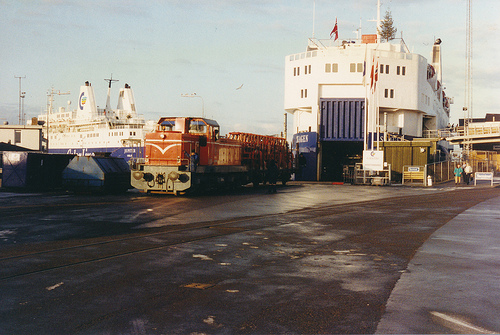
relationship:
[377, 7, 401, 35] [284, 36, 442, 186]
tree on building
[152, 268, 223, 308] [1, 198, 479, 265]
line on road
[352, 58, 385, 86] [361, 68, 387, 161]
flags on poles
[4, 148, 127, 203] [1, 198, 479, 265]
dumpsters on road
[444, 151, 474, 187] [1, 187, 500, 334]
people in road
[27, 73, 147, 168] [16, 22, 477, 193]
boat in background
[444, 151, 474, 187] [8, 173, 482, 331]
people on street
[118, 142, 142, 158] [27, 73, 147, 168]
name of boat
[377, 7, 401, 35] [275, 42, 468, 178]
tree on ship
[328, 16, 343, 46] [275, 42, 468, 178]
flag on ship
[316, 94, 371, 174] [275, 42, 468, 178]
door on ship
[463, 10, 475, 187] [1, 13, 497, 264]
tower in harbor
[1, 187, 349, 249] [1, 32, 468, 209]
shadows of ships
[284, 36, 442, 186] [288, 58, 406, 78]
building has windows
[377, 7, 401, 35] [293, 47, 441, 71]
tree on roof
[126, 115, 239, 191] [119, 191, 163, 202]
train on tracks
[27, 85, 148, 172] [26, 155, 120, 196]
boat in water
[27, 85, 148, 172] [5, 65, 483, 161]
boat in distance